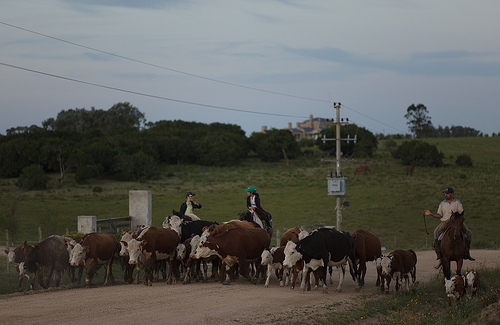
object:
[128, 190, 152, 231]
gray cement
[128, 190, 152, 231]
column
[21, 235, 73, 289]
cow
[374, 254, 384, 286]
cow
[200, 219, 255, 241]
cow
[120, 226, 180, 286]
cow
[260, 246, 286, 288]
cow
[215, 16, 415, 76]
clouds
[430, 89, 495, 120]
sky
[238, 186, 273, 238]
person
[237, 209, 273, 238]
horse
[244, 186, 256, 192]
hat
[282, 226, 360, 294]
cow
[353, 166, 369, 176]
horse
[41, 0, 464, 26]
sky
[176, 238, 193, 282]
cow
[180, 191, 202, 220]
person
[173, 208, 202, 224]
horse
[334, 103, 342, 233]
pole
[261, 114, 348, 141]
home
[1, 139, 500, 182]
hilltop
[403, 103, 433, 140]
tree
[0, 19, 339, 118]
electric lines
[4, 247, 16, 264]
cow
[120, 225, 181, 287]
brown cow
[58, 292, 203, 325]
dirt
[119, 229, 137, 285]
cow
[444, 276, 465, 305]
cow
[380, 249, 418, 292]
cow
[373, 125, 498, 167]
hilltop